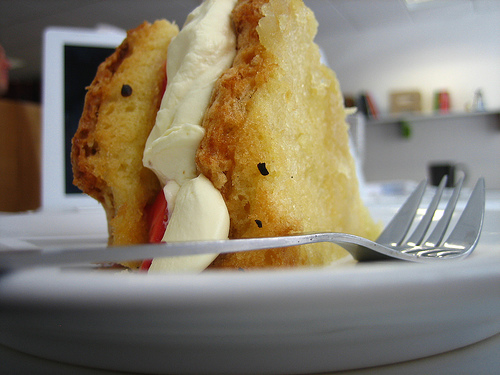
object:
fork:
[0, 170, 490, 294]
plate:
[0, 199, 499, 374]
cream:
[140, 0, 237, 275]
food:
[190, 0, 384, 269]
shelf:
[365, 107, 499, 124]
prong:
[439, 176, 488, 259]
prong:
[423, 176, 466, 246]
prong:
[373, 173, 428, 244]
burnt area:
[118, 83, 134, 98]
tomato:
[135, 190, 167, 272]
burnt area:
[256, 160, 270, 177]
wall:
[314, 10, 499, 193]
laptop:
[41, 25, 127, 234]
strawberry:
[136, 187, 169, 272]